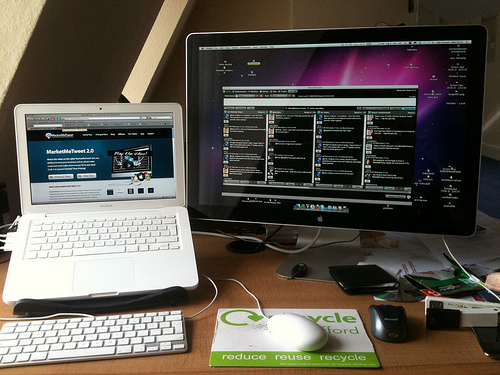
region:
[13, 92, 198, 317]
a laptop computer on a desk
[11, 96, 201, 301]
a white laptop computer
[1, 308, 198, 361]
a keyboard on a desk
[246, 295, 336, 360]
a mouse for a computer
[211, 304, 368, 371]
a mouse pad on a desk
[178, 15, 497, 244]
a large computer monitor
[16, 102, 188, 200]
a screen on a laptop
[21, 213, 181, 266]
a keyboard on a laptop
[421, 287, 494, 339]
a stapler on a desk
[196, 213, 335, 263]
Cords on a desk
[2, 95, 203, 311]
open white laptop on desk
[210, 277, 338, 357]
wired white computer mouse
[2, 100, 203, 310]
white apple macbook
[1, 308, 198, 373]
silver and white computer keyboard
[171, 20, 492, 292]
large silver imac computer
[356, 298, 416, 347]
black computer mouse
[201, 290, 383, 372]
green and white mousepad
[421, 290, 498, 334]
black and white stapler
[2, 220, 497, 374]
brown wooden desk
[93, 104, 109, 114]
camera lens on macbook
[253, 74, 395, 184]
the computer is on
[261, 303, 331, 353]
the mouse is white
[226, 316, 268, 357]
the mouse pad is green and white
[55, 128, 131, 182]
the laptop is on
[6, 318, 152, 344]
the keyboard is white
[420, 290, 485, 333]
the stapler is on its side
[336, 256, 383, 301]
the wallet is on the table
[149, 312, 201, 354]
the keyboard is on the table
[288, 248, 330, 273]
the stand is gray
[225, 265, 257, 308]
the cord is white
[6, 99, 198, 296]
A white laptop computer.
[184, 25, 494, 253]
A wide screen monitor.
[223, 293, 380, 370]
A mouse on a mousepad.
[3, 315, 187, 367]
A clear and white colored keyboard.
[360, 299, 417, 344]
A black wireless mouse.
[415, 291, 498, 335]
A stapler laying on it's side.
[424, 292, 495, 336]
A white and black stapler.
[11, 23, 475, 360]
A computer work station.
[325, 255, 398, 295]
A black wallet on a desk.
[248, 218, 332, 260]
Chords coming out of a computer.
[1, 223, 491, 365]
A wooden computer desk.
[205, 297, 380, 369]
A green and white mouse pad.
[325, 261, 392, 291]
A black wallet.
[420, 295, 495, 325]
A black and white stapler.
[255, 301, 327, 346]
A white computer mouse.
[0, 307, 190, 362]
A grey and white computer keyboard.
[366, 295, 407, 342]
A dark grey computer mouse.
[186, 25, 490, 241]
A black framed computer monitor.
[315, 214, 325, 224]
A silver apple logo.